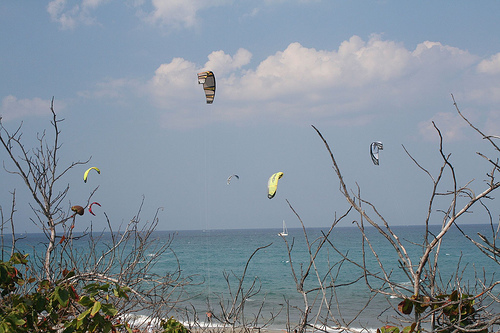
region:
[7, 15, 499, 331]
Exterior shot, daytime, showing signs of early spring, or fall-type weather.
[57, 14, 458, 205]
Grey-blue sky with moderate clouding.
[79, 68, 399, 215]
Kites, held aloft in the sky.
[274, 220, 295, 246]
Sailboat in the distance.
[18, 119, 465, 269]
Straggly bare twigs.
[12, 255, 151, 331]
Remaining green leaves of straggly trees.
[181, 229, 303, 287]
Blue, open water.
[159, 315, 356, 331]
Very light surf, approaching shore.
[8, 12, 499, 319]
Natural landscape, showing man-made objects, but no people.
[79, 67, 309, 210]
Two white and one patterned kite, making a triangle in the sky.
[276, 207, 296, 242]
A boat on the water.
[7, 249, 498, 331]
Bushes and brush.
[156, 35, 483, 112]
Clouds in the sky.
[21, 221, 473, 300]
A large body of water.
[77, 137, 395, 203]
Power kites in the air.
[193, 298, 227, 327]
A person flying his power kite.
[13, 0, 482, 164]
Big blue sky above.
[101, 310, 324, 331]
The beach.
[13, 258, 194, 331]
Leaves on the bushes.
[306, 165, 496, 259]
Sharp, bare branches.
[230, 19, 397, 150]
White clouds in the sky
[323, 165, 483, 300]
Branches on a bush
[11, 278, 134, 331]
Green leaves on bush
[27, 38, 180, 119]
Blue sky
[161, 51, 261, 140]
Object in the sky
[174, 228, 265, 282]
Blue ocean water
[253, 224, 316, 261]
White ship in the sea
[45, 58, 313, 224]
Multiple objects in the air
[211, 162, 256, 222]
One object in the distance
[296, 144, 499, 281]
Many branches of a bush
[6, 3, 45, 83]
this is the sky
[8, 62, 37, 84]
the sky is blue in color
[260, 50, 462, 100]
the sky has some clouds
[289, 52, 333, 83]
the cloud is white in color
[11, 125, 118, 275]
these are several branches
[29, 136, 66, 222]
the branches are leafless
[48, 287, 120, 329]
the leaves are green in color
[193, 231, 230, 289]
this is an ocean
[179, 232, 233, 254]
this is the water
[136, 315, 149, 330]
the sand is white in color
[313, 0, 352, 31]
part of the sky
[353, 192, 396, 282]
part of some tree branch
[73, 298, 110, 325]
part of some leaves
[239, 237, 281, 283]
part of a water body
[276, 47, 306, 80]
part of a cloud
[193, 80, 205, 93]
edge of a parachute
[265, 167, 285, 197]
surface of a parachute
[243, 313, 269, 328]
part of the shore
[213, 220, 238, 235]
edge of a water surface